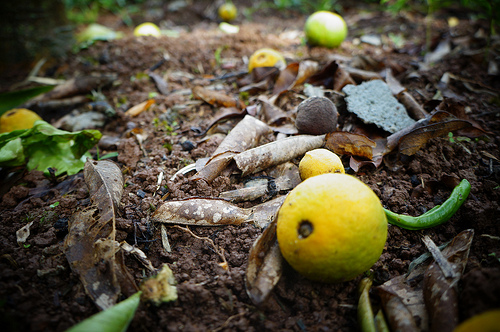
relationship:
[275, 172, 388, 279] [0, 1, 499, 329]
fruit on ground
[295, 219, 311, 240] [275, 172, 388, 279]
stem of fruit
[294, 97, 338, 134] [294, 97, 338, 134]
lemon that lemon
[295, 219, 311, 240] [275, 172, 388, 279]
stem on fruit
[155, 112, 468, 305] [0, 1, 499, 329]
leaves are on ground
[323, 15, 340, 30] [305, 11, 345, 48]
light on fruit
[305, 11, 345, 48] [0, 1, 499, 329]
fruit on ground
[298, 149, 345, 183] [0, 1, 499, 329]
fruit on ground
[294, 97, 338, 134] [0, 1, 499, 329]
lemon on ground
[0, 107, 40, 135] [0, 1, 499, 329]
lemon on ground